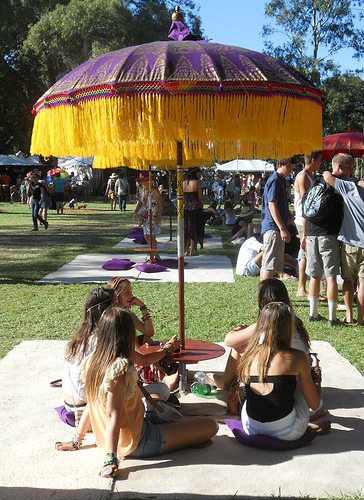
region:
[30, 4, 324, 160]
the multi colored umbrella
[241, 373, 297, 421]
the sleeveless black top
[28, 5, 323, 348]
the pole for the umbrella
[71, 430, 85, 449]
the bracelets on the wrist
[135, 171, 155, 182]
the red cowboy hat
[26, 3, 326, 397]
An elaborate sun-shading umbrella.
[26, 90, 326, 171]
Golden fabric fringe of umbrella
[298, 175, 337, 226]
A backpack with graphic design.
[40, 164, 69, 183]
A sun-shading umbrella held by hand.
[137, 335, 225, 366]
A small umbrella platform for drinks.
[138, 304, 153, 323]
Assorted braclets on girl's arm.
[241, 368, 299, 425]
A black haltar top.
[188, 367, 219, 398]
Empty soda bottles on the groun.d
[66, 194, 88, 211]
A small child petting a dog.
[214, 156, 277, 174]
The roof of an outdoor pavilion shelter.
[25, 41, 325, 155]
gold and purple umbrella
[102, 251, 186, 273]
purple pillows under the umbrella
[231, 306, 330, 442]
woman wearing black top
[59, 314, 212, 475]
woman wearing light orange top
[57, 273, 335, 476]
group of women sitting together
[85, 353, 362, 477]
shadows of the women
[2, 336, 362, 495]
white blanket the women are sitting on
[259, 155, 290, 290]
man wearing blue shirt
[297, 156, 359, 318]
man wearing black shirt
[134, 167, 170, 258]
woman wearing red hat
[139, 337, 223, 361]
a very small patio table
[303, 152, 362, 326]
two young men hugging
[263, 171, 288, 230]
a dark blue shirt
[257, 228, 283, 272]
a pair of grey shorts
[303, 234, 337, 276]
a pair of grey shorts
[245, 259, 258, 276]
a pair of blue shorts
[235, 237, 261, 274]
a white short sleeved shirt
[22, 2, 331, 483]
Five girls sitting under an umbrella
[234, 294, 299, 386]
Girl has long brown hair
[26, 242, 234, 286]
A white blanket on the grass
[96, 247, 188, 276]
Three pillows on the blanket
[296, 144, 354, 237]
Man is wearing a backpack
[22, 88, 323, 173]
Yellow fringe on an umbrella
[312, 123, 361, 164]
A red colored umbrella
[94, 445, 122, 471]
Bracelets around an arm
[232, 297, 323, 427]
Girl wearing a black top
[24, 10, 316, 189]
large purple and yellow umbrella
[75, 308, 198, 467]
woman sitting on a blanket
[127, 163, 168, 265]
woman wearing a red hat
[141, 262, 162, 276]
pillow on the ground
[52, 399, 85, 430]
pillow on the ground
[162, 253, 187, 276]
pillow on the ground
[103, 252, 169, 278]
square purple pillows on ground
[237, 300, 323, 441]
woman wearing black cutout top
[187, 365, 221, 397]
empty plastic soda bottles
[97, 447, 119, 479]
green bracelets on woman's hand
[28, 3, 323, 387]
large purple umbrella for shade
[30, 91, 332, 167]
bright yellow fringe on umbrella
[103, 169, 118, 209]
person wearing tan hat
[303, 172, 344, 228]
man wearing a black backpack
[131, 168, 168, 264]
woman wearing pink cowboy hat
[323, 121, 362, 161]
red and gold umbrella in background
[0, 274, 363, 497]
Five young women sitting on a concrete slab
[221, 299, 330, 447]
Young woman in black shirt sitting on purple pillow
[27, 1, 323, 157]
Richly colored shade umbrella with yellow tassels